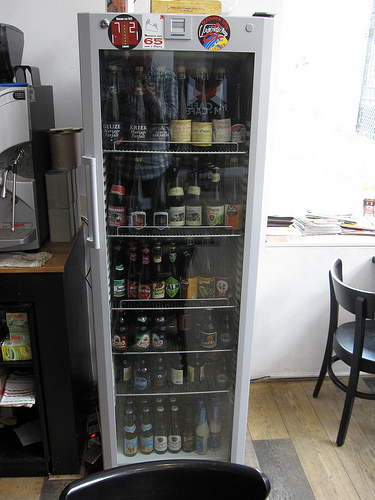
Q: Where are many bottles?
A: In the fridge.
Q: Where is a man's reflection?
A: On glass on the fridge.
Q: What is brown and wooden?
A: The floor.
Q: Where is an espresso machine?
A: On a cabinet.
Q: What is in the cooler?
A: Glass bottles.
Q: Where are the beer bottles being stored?
A: In the cooler.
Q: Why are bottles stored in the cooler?
A: To keep them cold.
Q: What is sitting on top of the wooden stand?
A: A coffee maker.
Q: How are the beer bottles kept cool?
A: They are stored in the refrigerator.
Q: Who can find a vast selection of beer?
A: Anyone opening the refrigerator cooler.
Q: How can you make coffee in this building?
A: By using the espresso machine.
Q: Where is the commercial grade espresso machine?
A: On the wooden table.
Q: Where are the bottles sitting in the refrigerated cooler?
A: On a shelf.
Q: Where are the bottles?
A: Fridge.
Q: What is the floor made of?
A: Wood.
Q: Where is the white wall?
A: Behind fridge.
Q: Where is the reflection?
A: Fridge door.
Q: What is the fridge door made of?
A: Glass.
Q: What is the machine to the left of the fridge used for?
A: Coffee drinks.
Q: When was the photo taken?
A: Afternoon.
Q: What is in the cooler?
A: Beer.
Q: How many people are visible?
A: Zero.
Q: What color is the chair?
A: Black.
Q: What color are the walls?
A: White.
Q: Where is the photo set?
A: Restaurant.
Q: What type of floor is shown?
A: Wood.